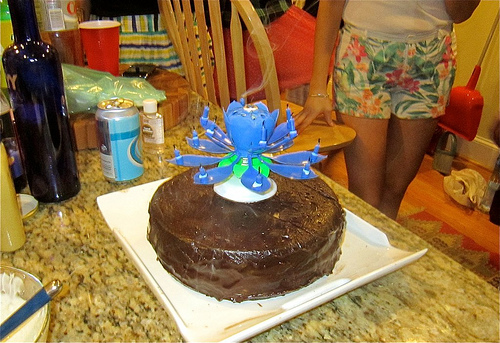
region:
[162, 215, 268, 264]
part of chocolate cake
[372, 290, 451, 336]
part of the countertop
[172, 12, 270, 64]
spindles on the chair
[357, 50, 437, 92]
design on woman's shorts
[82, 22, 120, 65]
a red plastic cup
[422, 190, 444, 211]
part of hardwood floor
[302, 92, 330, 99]
bracelet on woman's wrist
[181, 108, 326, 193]
topper on the cake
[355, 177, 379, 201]
knee on the woman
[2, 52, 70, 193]
a dark blue container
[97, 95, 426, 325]
cake with fancy complicated candle on top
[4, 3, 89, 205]
dark blue bottle of wine on table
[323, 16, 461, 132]
floral shorts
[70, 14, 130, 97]
red disposable solo cup on counter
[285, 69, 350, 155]
womans right hand resting on chair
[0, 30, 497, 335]
very cluttered countertop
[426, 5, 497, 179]
broom with red dustpan attached to the handle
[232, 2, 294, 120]
smoke curling from blown out candle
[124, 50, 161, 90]
cell phone sitting on lazy susan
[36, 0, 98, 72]
diet coke bottle sitting on lazy susan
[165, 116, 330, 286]
chocolate cake on the table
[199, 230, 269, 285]
frosting on the cake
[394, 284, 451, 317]
table below the cake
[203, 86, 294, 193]
blue thing on cake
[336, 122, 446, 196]
legs of a person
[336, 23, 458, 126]
shorts on the person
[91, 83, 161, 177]
can on the table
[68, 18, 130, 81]
red cup on table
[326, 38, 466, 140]
flower shorts on lady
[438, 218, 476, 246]
ground below the lady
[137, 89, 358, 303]
a cake nicely decorated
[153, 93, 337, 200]
a blue decoration on top of cake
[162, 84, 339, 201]
blue decoration holds candles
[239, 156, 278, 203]
candle is unlit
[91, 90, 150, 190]
can of beer on side a cake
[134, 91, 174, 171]
bottle of sanitizer next to a can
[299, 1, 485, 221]
person touching chair with right hand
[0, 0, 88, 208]
bottle of wine on a table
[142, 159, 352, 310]
chocolate cake is on a white container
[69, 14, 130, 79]
red cup on a table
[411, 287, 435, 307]
part of a surface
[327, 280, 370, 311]
edge of a tray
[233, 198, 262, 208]
edge of a plastic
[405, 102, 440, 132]
edge of a short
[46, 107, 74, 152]
part of a bottle